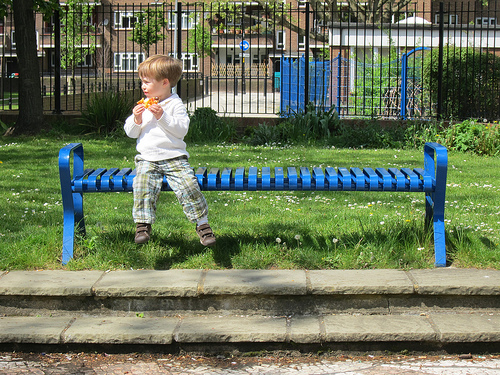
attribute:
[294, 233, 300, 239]
white flower — white 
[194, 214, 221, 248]
shoe — boy's 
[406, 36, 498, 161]
bush — tall green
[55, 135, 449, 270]
bench — long blue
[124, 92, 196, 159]
white shirt — boy's long sleeve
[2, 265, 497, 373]
staircase — concrete 